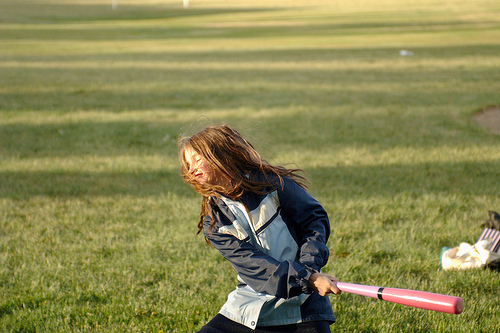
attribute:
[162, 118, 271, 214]
head — person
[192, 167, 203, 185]
mouth — person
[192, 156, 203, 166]
eye —  person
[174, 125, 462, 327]
girl — young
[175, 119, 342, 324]
girl — young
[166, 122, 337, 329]
girl — young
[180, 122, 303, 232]
hair — blonde, long, light brown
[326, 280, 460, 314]
bat — pink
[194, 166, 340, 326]
jacket — blue, grey, dark, white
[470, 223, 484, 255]
bag — striped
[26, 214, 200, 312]
grass — long, green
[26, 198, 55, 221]
sun — shines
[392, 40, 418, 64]
trash — laying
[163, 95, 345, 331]
girl — swinging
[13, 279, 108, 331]
grass — green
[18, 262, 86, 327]
patch — Small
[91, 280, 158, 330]
patch — Small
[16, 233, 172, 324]
grass — green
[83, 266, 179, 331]
grass — green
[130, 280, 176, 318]
patch — small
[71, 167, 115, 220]
patch — small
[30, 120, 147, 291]
grass — green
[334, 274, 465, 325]
bat — baseball, black, Pink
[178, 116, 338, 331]
child — small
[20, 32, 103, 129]
grass — green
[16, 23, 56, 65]
patch — small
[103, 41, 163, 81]
patch — small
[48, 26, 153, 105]
grass — green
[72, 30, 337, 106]
grass — green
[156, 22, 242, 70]
patch — small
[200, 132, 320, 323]
girl — small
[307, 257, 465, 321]
bat — small, pink, wooden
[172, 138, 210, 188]
face — white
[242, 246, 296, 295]
girl — small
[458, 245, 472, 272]
cloths — white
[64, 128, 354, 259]
field — large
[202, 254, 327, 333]
pants — black, cloth, long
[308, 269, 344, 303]
hand — small, white, slender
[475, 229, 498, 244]
bag — black striped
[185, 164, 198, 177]
nose — small, white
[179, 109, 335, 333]
girl — gray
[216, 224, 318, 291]
jacket — blue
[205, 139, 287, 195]
hair — long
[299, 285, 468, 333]
bat — pink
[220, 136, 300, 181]
hair — brown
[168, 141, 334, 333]
girl — little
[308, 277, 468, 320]
bat — pink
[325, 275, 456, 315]
bat — pink, toy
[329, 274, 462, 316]
bat — pink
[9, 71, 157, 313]
grass — mowed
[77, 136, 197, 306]
field — open, grassy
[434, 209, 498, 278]
stuff — piled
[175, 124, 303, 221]
hair — long, brown